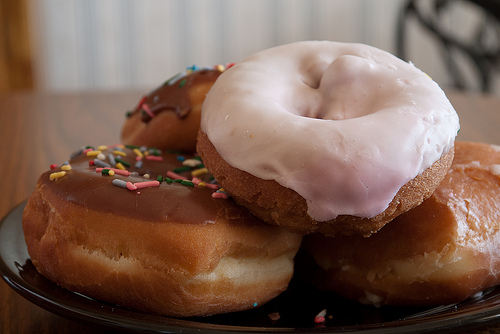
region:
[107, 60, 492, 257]
four donuts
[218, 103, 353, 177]
white frosting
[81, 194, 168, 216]
chocolate on the donut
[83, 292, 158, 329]
a black plate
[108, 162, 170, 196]
sprinkles on the donut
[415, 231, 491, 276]
glaze on the donut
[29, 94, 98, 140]
a brown table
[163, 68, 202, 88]
sprinkles on the donut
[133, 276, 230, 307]
bottom of the donut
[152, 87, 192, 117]
chocolate on the donut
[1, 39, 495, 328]
Four doughnuts are together.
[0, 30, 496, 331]
The doughnuts are on a plate.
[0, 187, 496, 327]
The plate is black.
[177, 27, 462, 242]
The doughnut is frosted.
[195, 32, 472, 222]
The frosting is white.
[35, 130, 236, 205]
The doughnut has sprinkles.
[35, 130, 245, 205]
The sprinkles are multicolored.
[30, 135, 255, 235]
Chocolate frosting is on the doughnut.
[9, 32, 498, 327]
Four doughnuts are on the plate.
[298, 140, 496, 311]
The doughnut is a honey dipped one.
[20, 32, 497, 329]
Doughnuts on a plate.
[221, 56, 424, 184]
The icing is white.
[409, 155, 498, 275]
The doughnut is glazed.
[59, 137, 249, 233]
The icing is brown.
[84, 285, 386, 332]
The plate is black.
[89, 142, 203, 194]
Sprinkles on the doughnut.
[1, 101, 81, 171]
The table is wooden.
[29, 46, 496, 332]
Four doughnuts on the plate.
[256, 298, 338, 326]
Sprinkles on the plate.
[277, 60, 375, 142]
Hole in the doughnut.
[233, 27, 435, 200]
donut with white frosting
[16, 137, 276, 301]
donut with rainbow sprinkles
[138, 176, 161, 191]
small piece of rainbow sprinkle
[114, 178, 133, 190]
small piece of rainbow sprinkle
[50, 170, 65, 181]
small piece of rainbow sprinkle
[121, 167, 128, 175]
small piece of rainbow sprinkle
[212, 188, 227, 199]
small piece of rainbow sprinkle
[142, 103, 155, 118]
small piece of rainbow sprinkle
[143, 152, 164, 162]
small piece of rainbow sprinkle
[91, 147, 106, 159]
small piece of rainbow sprinkle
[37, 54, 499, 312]
A plate of delicious looking donuts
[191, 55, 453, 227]
A donut with white frosting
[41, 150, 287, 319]
A donut with sprinkles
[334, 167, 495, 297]
A normal glazed donut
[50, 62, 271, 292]
Two donuts with sprinkles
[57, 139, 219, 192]
Multicolored sprinkles on the donuts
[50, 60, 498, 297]
Four assorted donuts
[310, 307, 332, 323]
Crumbs on the plate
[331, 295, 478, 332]
A black plate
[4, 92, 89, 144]
A wooden table